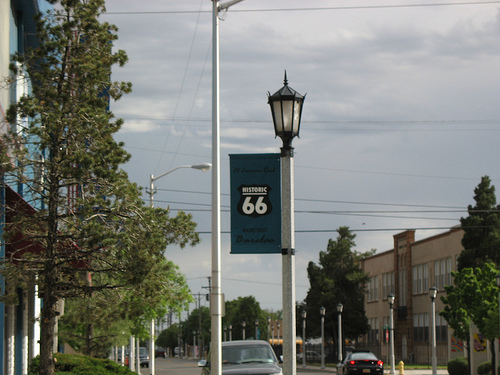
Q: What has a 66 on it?
A: The blue sign.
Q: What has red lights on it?
A: The car.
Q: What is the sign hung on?
A: A lamp post.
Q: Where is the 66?
A: On the sign.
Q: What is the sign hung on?
A: A lamp post.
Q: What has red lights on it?
A: A car.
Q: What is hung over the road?
A: Power lines.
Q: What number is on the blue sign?
A: 66.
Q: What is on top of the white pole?
A: A light.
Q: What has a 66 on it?
A: The blue sign.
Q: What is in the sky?
A: Clouds.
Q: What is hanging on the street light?
A: A sign.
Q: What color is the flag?
A: Blue.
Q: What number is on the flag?
A: 66.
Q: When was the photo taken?
A: Daytime.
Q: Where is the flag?
A: On a pole.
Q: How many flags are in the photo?
A: One.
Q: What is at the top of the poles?
A: Lights.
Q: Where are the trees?
A: Lining the street.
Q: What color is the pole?
A: White.